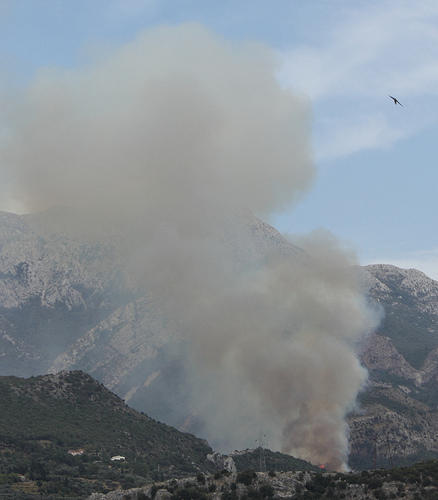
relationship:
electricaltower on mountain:
[253, 431, 269, 471] [199, 445, 335, 472]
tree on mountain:
[186, 451, 263, 499] [207, 445, 331, 473]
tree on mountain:
[236, 459, 259, 490] [12, 379, 405, 480]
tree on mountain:
[220, 469, 230, 477] [1, 369, 436, 496]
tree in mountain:
[212, 466, 233, 479] [0, 361, 331, 470]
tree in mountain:
[192, 475, 205, 485] [25, 360, 370, 496]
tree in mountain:
[75, 461, 97, 477] [25, 360, 370, 496]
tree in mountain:
[20, 458, 46, 480] [25, 360, 370, 496]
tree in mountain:
[150, 414, 166, 433] [25, 360, 370, 496]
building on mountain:
[67, 447, 86, 455] [1, 368, 206, 499]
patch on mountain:
[0, 285, 147, 377] [0, 182, 436, 470]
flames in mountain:
[318, 464, 326, 469] [1, 207, 436, 494]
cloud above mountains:
[0, 0, 438, 283] [0, 206, 437, 498]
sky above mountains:
[1, 8, 437, 295] [0, 206, 437, 498]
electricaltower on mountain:
[251, 431, 271, 471] [1, 207, 436, 494]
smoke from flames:
[6, 23, 380, 471] [316, 463, 326, 469]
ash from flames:
[249, 434, 265, 448] [316, 463, 326, 469]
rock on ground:
[110, 453, 126, 463] [58, 429, 174, 492]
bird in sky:
[388, 92, 405, 110] [1, 2, 435, 193]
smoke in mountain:
[122, 159, 361, 474] [1, 207, 436, 494]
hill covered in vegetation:
[7, 371, 106, 422] [2, 366, 220, 497]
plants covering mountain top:
[76, 408, 136, 443] [3, 205, 437, 376]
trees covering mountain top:
[183, 472, 206, 494] [3, 205, 437, 376]